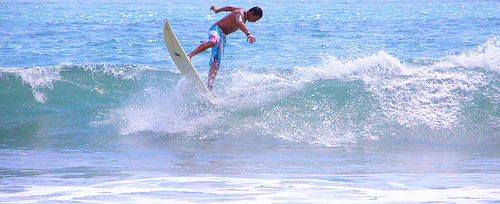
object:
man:
[187, 5, 263, 98]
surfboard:
[163, 19, 213, 100]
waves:
[0, 64, 499, 136]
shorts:
[200, 25, 227, 70]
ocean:
[0, 0, 499, 204]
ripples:
[5, 18, 480, 67]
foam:
[0, 37, 499, 147]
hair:
[249, 6, 263, 18]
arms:
[210, 5, 257, 44]